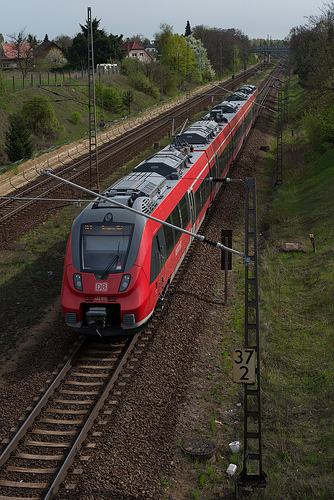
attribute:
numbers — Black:
[233, 346, 255, 383]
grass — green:
[194, 305, 238, 492]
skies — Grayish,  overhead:
[2, 3, 326, 38]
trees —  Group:
[280, 4, 333, 149]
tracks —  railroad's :
[0, 330, 136, 493]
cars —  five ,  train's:
[55, 85, 261, 340]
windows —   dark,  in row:
[162, 193, 191, 248]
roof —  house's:
[0, 40, 35, 60]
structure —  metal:
[87, 7, 100, 183]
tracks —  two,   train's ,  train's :
[2, 337, 145, 497]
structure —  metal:
[87, 7, 97, 197]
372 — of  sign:
[231, 350, 254, 382]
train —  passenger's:
[59, 81, 261, 338]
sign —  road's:
[223, 227, 231, 269]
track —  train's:
[2, 333, 148, 496]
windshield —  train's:
[82, 222, 133, 269]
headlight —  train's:
[117, 273, 130, 292]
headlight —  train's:
[73, 273, 81, 291]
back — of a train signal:
[218, 228, 233, 268]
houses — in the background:
[96, 38, 159, 76]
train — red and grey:
[58, 106, 255, 344]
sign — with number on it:
[229, 347, 255, 385]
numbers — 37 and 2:
[231, 348, 252, 383]